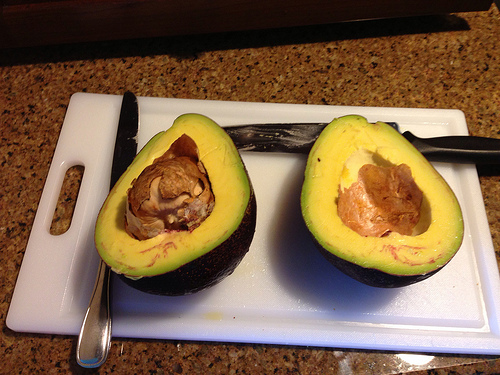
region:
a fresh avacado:
[76, 96, 498, 330]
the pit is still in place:
[92, 106, 279, 293]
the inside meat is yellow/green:
[96, 122, 251, 262]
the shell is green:
[156, 120, 263, 301]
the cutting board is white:
[81, 137, 496, 341]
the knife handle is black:
[257, 130, 497, 169]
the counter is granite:
[13, 45, 415, 81]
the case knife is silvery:
[66, 80, 146, 372]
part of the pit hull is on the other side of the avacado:
[321, 159, 406, 246]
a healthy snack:
[74, 102, 496, 325]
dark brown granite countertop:
[403, 39, 490, 94]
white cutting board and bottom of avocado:
[279, 277, 406, 342]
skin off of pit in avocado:
[356, 177, 396, 216]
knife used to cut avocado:
[273, 113, 302, 159]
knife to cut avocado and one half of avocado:
[94, 123, 257, 302]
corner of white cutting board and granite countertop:
[24, 71, 101, 173]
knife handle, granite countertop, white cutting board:
[422, 73, 498, 180]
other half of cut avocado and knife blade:
[277, 99, 461, 338]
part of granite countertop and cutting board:
[0, 263, 55, 350]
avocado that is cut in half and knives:
[36, 79, 486, 358]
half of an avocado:
[78, 91, 258, 298]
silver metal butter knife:
[93, 78, 151, 372]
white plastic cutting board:
[33, 71, 477, 350]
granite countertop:
[14, 43, 454, 112]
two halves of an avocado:
[101, 94, 444, 291]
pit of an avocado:
[127, 146, 214, 236]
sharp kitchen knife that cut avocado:
[158, 96, 493, 171]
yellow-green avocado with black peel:
[293, 110, 461, 290]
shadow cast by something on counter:
[7, 10, 471, 61]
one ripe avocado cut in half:
[98, 92, 458, 309]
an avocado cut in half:
[103, 112, 458, 293]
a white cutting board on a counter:
[1, 78, 96, 373]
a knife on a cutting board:
[78, 81, 134, 369]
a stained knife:
[222, 92, 319, 163]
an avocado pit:
[123, 154, 215, 232]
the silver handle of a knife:
[71, 265, 125, 374]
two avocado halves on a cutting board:
[105, 104, 466, 316]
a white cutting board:
[45, 163, 78, 372]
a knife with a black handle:
[217, 110, 497, 160]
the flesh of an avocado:
[316, 135, 438, 253]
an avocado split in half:
[70, 103, 473, 315]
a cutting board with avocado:
[52, 82, 480, 357]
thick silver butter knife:
[67, 76, 137, 368]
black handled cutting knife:
[185, 79, 495, 179]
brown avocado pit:
[116, 142, 239, 257]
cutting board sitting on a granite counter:
[13, 71, 473, 373]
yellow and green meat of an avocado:
[171, 113, 274, 177]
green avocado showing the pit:
[79, 109, 272, 297]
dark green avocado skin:
[171, 197, 283, 294]